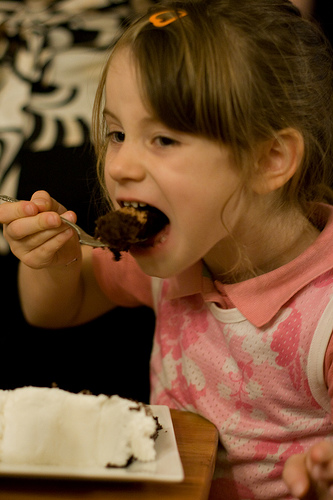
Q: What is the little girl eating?
A: Cake.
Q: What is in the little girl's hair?
A: Barrette.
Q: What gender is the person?
A: Female.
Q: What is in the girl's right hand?
A: Fork.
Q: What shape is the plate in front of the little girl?
A: Square.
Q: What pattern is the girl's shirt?
A: Floral.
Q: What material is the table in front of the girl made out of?
A: Wood.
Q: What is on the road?
A: Cake.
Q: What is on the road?
A: Cake.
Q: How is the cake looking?
A: White.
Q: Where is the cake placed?
A: Table.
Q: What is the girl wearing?
A: Dress.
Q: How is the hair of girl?
A: Brown.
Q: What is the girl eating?
A: Cake.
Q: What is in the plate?
A: Pastry.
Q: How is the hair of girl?
A: Hanging.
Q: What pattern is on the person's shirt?
A: Floral.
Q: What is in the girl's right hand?
A: Fork.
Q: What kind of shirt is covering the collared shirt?
A: Tank top.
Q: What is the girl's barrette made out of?
A: Metal.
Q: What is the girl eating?
A: Chocolate cake.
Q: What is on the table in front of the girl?
A: Plate of cake.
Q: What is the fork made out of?
A: Metal.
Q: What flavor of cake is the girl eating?
A: Chocolate.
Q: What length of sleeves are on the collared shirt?
A: Short sleeves.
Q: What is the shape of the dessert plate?
A: Square.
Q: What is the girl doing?
A: Eating.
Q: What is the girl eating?
A: Cake.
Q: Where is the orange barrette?
A: In the girl's hair.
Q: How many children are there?
A: One.